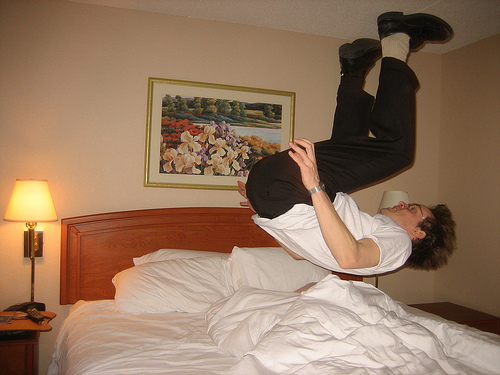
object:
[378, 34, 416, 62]
sock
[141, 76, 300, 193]
frame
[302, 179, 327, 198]
silver watch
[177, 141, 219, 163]
flowers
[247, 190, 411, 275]
tee shirt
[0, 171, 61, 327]
lamp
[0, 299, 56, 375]
nightstand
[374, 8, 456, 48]
shoe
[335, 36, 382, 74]
shoe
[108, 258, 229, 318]
pillow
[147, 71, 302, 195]
picture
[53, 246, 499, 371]
comforter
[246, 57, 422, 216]
pants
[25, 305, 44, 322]
remote control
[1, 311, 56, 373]
table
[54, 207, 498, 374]
bed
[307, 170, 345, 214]
wrist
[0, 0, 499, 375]
wall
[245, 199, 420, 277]
shirt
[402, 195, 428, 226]
eyeglasses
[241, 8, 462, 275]
man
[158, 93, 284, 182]
painting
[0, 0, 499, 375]
hotel room